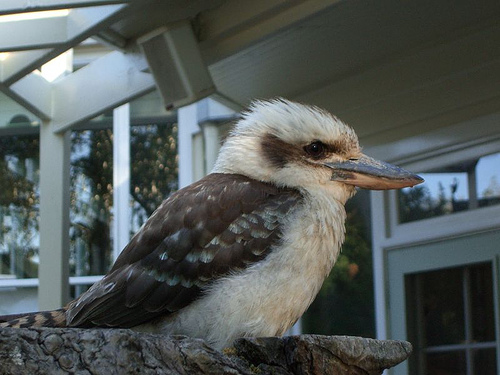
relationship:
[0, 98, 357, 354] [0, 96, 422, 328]
feather on bird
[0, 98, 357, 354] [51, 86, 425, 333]
feather on bird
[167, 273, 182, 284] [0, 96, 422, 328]
white feathers on bird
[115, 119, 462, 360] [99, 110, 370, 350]
feather on bird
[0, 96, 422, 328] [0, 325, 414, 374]
bird on perch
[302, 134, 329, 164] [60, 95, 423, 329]
eye of kookaburra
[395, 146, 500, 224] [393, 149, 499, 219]
reflection of window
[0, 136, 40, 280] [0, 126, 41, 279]
tree behind window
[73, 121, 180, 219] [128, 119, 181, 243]
tree behind window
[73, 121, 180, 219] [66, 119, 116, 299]
tree behind window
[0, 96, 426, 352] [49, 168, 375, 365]
bird has wing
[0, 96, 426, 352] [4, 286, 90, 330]
bird has tail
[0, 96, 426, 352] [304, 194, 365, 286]
bird has breast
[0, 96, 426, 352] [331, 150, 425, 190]
bird has beak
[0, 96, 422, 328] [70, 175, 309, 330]
bird has black feathers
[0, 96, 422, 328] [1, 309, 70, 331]
bird has tail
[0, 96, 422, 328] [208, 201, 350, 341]
bird has underbelly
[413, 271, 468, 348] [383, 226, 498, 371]
pane on door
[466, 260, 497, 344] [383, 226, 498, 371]
pane on door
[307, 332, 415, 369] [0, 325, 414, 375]
stone in stone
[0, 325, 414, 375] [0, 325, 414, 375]
stone in stone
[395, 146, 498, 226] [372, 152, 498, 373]
reflection on window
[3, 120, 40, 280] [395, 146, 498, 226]
tree has reflection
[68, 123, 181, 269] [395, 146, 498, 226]
tree has reflection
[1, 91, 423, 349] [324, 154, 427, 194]
bird has beak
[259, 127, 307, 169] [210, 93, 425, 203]
spot on head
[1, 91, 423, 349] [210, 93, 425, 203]
bird has head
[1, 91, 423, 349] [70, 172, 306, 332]
bird has wing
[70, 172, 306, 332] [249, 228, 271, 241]
wing has spot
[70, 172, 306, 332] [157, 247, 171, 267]
wing has spot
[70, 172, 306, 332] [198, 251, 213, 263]
wing has spot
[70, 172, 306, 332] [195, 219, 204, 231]
wing has spot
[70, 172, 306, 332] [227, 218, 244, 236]
wing has spot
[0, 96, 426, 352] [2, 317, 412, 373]
bird on perch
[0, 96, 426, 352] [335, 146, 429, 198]
bird has beak